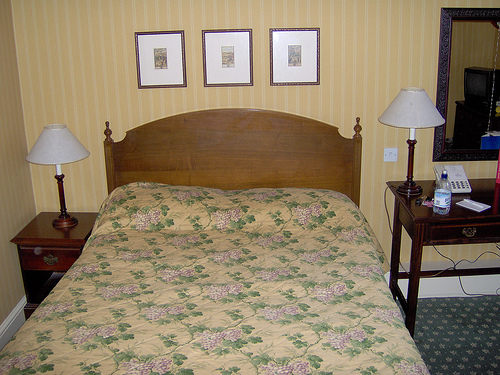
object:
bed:
[0, 106, 432, 373]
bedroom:
[0, 1, 499, 372]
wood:
[381, 179, 499, 340]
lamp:
[375, 87, 445, 199]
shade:
[374, 85, 446, 133]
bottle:
[430, 169, 450, 214]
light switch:
[381, 146, 396, 164]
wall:
[0, 1, 499, 298]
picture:
[130, 29, 186, 90]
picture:
[200, 28, 252, 88]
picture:
[268, 26, 320, 87]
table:
[384, 177, 499, 339]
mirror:
[430, 7, 499, 165]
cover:
[2, 181, 434, 374]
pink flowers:
[242, 259, 301, 283]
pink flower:
[182, 319, 251, 359]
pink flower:
[203, 202, 248, 234]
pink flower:
[364, 304, 408, 323]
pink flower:
[90, 272, 150, 307]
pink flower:
[121, 204, 168, 235]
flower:
[196, 324, 248, 353]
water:
[430, 204, 447, 216]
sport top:
[439, 168, 448, 181]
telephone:
[431, 164, 471, 195]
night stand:
[9, 211, 100, 320]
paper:
[453, 198, 491, 214]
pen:
[463, 198, 485, 210]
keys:
[414, 195, 435, 207]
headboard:
[102, 107, 362, 207]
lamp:
[22, 123, 91, 229]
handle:
[458, 224, 478, 240]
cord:
[430, 243, 498, 298]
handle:
[40, 251, 62, 267]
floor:
[395, 292, 499, 374]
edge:
[380, 181, 418, 223]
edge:
[356, 204, 434, 375]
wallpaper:
[0, 1, 499, 326]